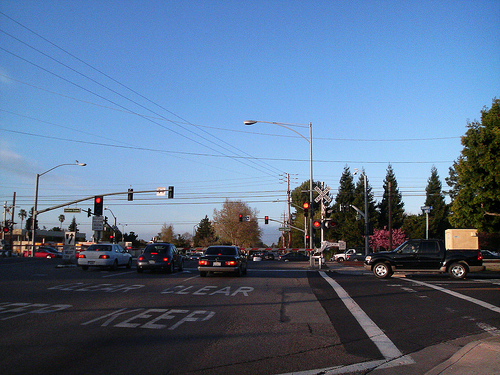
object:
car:
[195, 245, 248, 277]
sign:
[63, 207, 83, 213]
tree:
[96, 223, 119, 239]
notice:
[0, 280, 255, 330]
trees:
[380, 164, 407, 227]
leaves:
[227, 208, 241, 228]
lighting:
[17, 152, 193, 232]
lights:
[238, 211, 305, 224]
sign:
[92, 215, 107, 232]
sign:
[312, 183, 331, 203]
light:
[94, 195, 103, 215]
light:
[312, 218, 320, 227]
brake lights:
[223, 259, 238, 265]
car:
[76, 242, 133, 269]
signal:
[302, 201, 337, 229]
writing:
[83, 283, 254, 329]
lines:
[318, 268, 415, 367]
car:
[22, 248, 60, 258]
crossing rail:
[253, 243, 372, 263]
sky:
[0, 0, 500, 242]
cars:
[137, 240, 186, 272]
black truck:
[365, 237, 484, 279]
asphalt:
[224, 305, 294, 356]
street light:
[242, 120, 318, 264]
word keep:
[81, 306, 216, 331]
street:
[0, 267, 500, 374]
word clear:
[160, 284, 256, 297]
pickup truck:
[365, 239, 485, 279]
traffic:
[49, 230, 259, 286]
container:
[445, 227, 479, 249]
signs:
[305, 185, 331, 207]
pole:
[314, 200, 327, 265]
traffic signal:
[90, 194, 99, 216]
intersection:
[46, 266, 499, 373]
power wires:
[166, 190, 288, 206]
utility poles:
[25, 110, 327, 273]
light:
[242, 118, 257, 124]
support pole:
[305, 118, 317, 281]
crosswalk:
[316, 265, 407, 368]